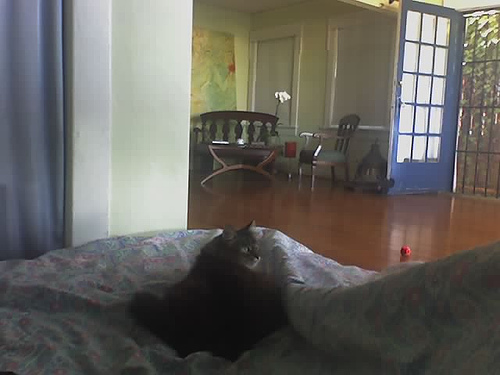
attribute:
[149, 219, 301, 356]
cat — looking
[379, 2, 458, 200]
blue door — open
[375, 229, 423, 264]
ball — red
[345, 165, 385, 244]
ground — grey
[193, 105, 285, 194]
bench — wooden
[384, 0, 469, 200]
door — open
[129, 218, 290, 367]
cat — lying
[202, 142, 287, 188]
table — brown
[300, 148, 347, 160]
seat — green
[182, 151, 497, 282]
floor — dark, wooden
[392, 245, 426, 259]
ball — red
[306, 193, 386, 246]
floor — wooden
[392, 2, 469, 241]
door — blue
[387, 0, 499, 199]
door — metal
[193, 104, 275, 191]
table — coffee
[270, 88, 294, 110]
flower — white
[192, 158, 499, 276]
floor — wooden